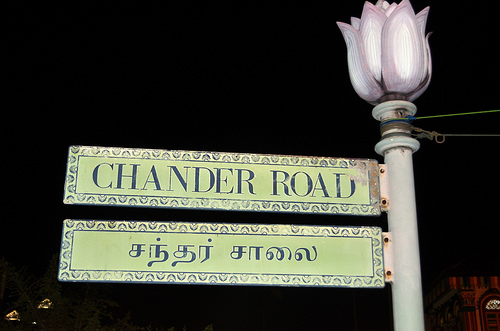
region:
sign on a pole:
[132, 96, 498, 303]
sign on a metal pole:
[228, 84, 496, 328]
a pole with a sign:
[279, 101, 490, 325]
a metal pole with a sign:
[317, 136, 471, 313]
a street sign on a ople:
[329, 117, 446, 322]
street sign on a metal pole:
[296, 86, 498, 326]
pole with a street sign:
[322, 132, 498, 305]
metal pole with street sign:
[332, 115, 498, 292]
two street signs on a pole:
[129, 100, 372, 325]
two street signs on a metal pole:
[94, 92, 488, 318]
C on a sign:
[87, 154, 119, 204]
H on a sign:
[116, 161, 138, 198]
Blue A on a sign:
[142, 158, 167, 195]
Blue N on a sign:
[168, 160, 191, 202]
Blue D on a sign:
[191, 162, 220, 201]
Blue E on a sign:
[211, 165, 236, 197]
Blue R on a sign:
[236, 167, 258, 199]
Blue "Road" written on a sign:
[266, 167, 352, 198]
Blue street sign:
[89, 205, 354, 282]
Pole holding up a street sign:
[386, 124, 446, 326]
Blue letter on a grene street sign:
[84, 148, 113, 195]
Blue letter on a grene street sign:
[107, 157, 137, 195]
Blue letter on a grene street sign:
[139, 159, 162, 201]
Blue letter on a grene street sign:
[162, 157, 195, 202]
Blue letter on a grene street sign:
[190, 159, 215, 200]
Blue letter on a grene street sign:
[205, 154, 238, 202]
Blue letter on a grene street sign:
[229, 162, 256, 199]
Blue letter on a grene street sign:
[260, 159, 293, 201]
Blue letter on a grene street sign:
[288, 167, 317, 202]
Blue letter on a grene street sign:
[311, 171, 332, 222]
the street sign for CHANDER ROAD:
[47, 129, 389, 220]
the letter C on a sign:
[88, 154, 115, 194]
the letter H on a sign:
[111, 158, 145, 193]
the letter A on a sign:
[140, 159, 163, 192]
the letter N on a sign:
[161, 161, 193, 188]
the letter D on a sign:
[190, 164, 213, 194]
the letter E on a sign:
[212, 165, 238, 194]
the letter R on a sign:
[230, 165, 255, 196]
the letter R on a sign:
[265, 165, 292, 198]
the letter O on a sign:
[288, 167, 312, 197]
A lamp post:
[332, 9, 447, 328]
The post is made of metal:
[384, 126, 425, 326]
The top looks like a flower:
[336, 6, 441, 113]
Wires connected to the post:
[393, 97, 496, 154]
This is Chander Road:
[63, 134, 380, 219]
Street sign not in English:
[57, 211, 434, 304]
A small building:
[428, 260, 495, 330]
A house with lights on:
[2, 281, 109, 328]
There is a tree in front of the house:
[4, 270, 120, 327]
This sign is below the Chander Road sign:
[49, 219, 379, 286]